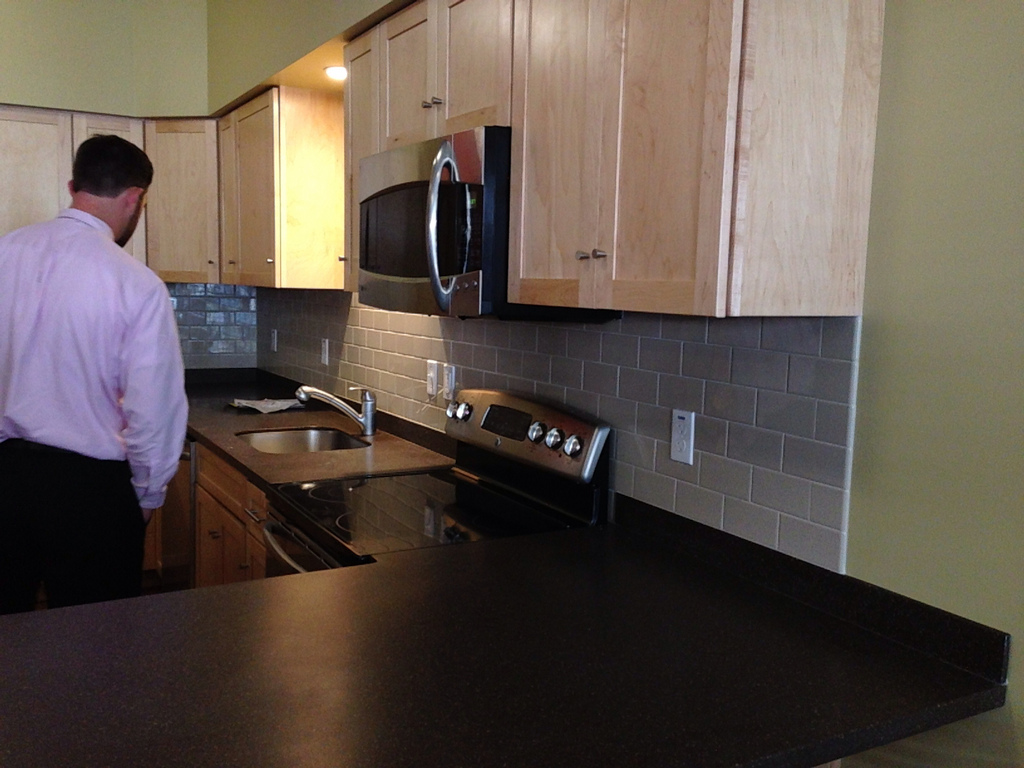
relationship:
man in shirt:
[13, 119, 199, 586] [6, 198, 203, 507]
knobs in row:
[516, 410, 590, 469] [512, 406, 590, 458]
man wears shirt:
[13, 119, 199, 586] [6, 198, 203, 507]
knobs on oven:
[528, 421, 548, 443] [266, 389, 616, 567]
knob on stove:
[558, 426, 584, 459] [262, 368, 625, 597]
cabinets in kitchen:
[11, 9, 846, 321] [11, 16, 994, 734]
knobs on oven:
[528, 421, 548, 443] [258, 363, 626, 584]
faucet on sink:
[282, 370, 376, 446] [230, 413, 373, 461]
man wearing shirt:
[13, 119, 199, 586] [0, 206, 192, 510]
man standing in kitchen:
[13, 119, 199, 586] [11, 16, 994, 734]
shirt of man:
[6, 198, 203, 507] [2, 103, 199, 605]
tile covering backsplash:
[778, 513, 847, 576] [255, 286, 858, 575]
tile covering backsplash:
[804, 480, 848, 532] [255, 286, 858, 575]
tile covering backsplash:
[776, 431, 850, 494] [255, 286, 858, 575]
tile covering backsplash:
[814, 398, 858, 448] [255, 286, 858, 575]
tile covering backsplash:
[784, 353, 860, 408] [255, 286, 858, 575]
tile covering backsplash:
[817, 314, 863, 360] [255, 286, 858, 575]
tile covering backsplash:
[719, 495, 784, 554] [255, 286, 858, 575]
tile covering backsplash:
[536, 323, 569, 354] [255, 286, 858, 575]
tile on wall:
[258, 284, 851, 578] [212, 1, 982, 719]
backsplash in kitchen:
[176, 288, 868, 569] [11, 16, 994, 734]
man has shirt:
[13, 119, 199, 586] [6, 198, 203, 507]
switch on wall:
[443, 363, 456, 400] [212, 9, 986, 599]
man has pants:
[0, 132, 192, 611] [14, 430, 149, 588]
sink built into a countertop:
[232, 409, 380, 466] [24, 353, 982, 734]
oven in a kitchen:
[266, 389, 616, 567] [11, 16, 994, 734]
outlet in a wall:
[660, 400, 702, 474] [212, 9, 986, 599]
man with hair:
[13, 119, 199, 586] [63, 126, 157, 194]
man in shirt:
[13, 119, 199, 586] [0, 206, 192, 510]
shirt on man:
[0, 206, 192, 510] [13, 119, 199, 586]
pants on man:
[14, 430, 149, 588] [13, 119, 199, 586]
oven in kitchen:
[264, 368, 617, 561] [11, 16, 994, 734]